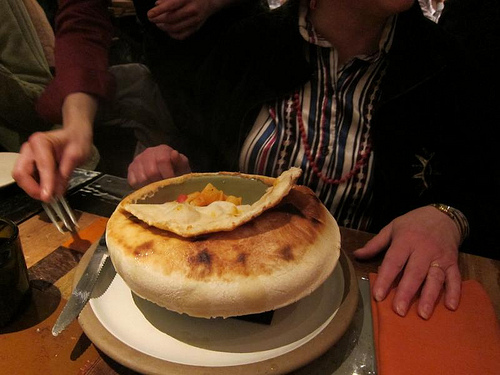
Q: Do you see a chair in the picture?
A: No, there are no chairs.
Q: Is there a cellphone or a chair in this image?
A: No, there are no chairs or cell phones.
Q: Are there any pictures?
A: No, there are no pictures.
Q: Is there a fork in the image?
A: Yes, there is a fork.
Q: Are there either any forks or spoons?
A: Yes, there is a fork.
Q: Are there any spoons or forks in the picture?
A: Yes, there is a fork.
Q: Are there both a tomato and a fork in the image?
A: No, there is a fork but no tomatoes.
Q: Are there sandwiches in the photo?
A: No, there are no sandwiches.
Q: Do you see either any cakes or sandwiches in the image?
A: No, there are no sandwiches or cakes.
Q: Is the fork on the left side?
A: Yes, the fork is on the left of the image.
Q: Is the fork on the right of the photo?
A: No, the fork is on the left of the image.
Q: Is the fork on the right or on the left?
A: The fork is on the left of the image.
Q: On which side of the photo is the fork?
A: The fork is on the left of the image.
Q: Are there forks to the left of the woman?
A: Yes, there is a fork to the left of the woman.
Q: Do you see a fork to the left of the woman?
A: Yes, there is a fork to the left of the woman.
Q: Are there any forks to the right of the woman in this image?
A: No, the fork is to the left of the woman.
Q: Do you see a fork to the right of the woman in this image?
A: No, the fork is to the left of the woman.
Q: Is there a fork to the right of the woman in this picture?
A: No, the fork is to the left of the woman.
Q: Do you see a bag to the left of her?
A: No, there is a fork to the left of the woman.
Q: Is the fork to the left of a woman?
A: Yes, the fork is to the left of a woman.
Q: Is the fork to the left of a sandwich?
A: No, the fork is to the left of a woman.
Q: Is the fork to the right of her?
A: No, the fork is to the left of a woman.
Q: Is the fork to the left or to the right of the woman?
A: The fork is to the left of the woman.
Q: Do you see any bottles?
A: No, there are no bottles.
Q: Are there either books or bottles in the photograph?
A: No, there are no bottles or books.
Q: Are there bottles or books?
A: No, there are no bottles or books.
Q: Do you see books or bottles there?
A: No, there are no bottles or books.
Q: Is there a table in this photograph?
A: Yes, there is a table.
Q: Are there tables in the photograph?
A: Yes, there is a table.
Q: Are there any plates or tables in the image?
A: Yes, there is a table.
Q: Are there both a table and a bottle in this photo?
A: No, there is a table but no bottles.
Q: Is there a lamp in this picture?
A: No, there are no lamps.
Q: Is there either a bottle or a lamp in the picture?
A: No, there are no lamps or bottles.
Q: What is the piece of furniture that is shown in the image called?
A: The piece of furniture is a table.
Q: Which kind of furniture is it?
A: The piece of furniture is a table.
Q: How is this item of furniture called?
A: This is a table.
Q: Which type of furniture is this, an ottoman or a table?
A: This is a table.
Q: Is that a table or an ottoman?
A: That is a table.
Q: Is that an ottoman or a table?
A: That is a table.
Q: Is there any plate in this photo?
A: Yes, there is a plate.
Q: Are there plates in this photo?
A: Yes, there is a plate.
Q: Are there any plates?
A: Yes, there is a plate.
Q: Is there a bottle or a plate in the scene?
A: Yes, there is a plate.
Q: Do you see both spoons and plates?
A: No, there is a plate but no spoons.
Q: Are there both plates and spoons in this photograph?
A: No, there is a plate but no spoons.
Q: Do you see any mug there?
A: No, there are no mugs.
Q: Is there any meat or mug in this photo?
A: No, there are no mugs or meat.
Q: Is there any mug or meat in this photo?
A: No, there are no mugs or meat.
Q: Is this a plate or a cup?
A: This is a plate.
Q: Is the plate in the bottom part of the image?
A: Yes, the plate is in the bottom of the image.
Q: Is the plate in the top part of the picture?
A: No, the plate is in the bottom of the image.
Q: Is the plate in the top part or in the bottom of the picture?
A: The plate is in the bottom of the image.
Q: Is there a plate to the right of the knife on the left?
A: Yes, there is a plate to the right of the knife.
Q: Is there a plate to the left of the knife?
A: No, the plate is to the right of the knife.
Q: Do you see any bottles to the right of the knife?
A: No, there is a plate to the right of the knife.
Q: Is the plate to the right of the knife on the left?
A: Yes, the plate is to the right of the knife.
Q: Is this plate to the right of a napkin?
A: No, the plate is to the right of the knife.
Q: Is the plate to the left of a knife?
A: No, the plate is to the right of a knife.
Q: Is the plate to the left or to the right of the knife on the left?
A: The plate is to the right of the knife.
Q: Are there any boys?
A: No, there are no boys.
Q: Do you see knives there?
A: Yes, there is a knife.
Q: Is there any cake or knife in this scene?
A: Yes, there is a knife.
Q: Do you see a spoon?
A: No, there are no spoons.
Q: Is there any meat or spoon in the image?
A: No, there are no spoons or meat.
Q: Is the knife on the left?
A: Yes, the knife is on the left of the image.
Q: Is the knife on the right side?
A: No, the knife is on the left of the image.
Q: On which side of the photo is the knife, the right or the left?
A: The knife is on the left of the image.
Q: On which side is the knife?
A: The knife is on the left of the image.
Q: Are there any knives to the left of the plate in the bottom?
A: Yes, there is a knife to the left of the plate.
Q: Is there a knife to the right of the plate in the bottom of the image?
A: No, the knife is to the left of the plate.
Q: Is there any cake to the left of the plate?
A: No, there is a knife to the left of the plate.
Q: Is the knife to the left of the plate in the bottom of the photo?
A: Yes, the knife is to the left of the plate.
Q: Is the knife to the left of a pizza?
A: No, the knife is to the left of the plate.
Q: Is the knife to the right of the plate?
A: No, the knife is to the left of the plate.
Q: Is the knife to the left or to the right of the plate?
A: The knife is to the left of the plate.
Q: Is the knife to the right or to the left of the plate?
A: The knife is to the left of the plate.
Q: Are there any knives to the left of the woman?
A: Yes, there is a knife to the left of the woman.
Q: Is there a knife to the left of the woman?
A: Yes, there is a knife to the left of the woman.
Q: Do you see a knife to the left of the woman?
A: Yes, there is a knife to the left of the woman.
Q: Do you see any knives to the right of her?
A: No, the knife is to the left of the woman.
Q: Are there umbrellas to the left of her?
A: No, there is a knife to the left of the woman.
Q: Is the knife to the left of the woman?
A: Yes, the knife is to the left of the woman.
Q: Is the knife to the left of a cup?
A: No, the knife is to the left of the woman.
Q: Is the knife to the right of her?
A: No, the knife is to the left of the woman.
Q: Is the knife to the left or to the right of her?
A: The knife is to the left of the woman.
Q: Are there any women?
A: Yes, there is a woman.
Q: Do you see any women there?
A: Yes, there is a woman.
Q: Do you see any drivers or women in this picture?
A: Yes, there is a woman.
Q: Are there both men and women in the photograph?
A: No, there is a woman but no men.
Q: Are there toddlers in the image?
A: No, there are no toddlers.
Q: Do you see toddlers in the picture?
A: No, there are no toddlers.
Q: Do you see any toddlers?
A: No, there are no toddlers.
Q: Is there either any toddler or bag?
A: No, there are no toddlers or bags.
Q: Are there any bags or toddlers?
A: No, there are no toddlers or bags.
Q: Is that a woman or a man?
A: That is a woman.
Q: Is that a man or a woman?
A: That is a woman.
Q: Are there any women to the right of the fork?
A: Yes, there is a woman to the right of the fork.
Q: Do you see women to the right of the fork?
A: Yes, there is a woman to the right of the fork.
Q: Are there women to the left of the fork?
A: No, the woman is to the right of the fork.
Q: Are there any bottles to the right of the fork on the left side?
A: No, there is a woman to the right of the fork.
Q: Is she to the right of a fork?
A: Yes, the woman is to the right of a fork.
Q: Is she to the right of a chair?
A: No, the woman is to the right of a fork.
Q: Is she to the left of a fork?
A: No, the woman is to the right of a fork.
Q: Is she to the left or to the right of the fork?
A: The woman is to the right of the fork.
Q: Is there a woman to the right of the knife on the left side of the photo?
A: Yes, there is a woman to the right of the knife.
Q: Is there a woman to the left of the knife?
A: No, the woman is to the right of the knife.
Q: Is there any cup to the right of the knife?
A: No, there is a woman to the right of the knife.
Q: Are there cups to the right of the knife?
A: No, there is a woman to the right of the knife.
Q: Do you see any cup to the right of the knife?
A: No, there is a woman to the right of the knife.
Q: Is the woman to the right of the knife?
A: Yes, the woman is to the right of the knife.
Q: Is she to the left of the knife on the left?
A: No, the woman is to the right of the knife.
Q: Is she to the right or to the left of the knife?
A: The woman is to the right of the knife.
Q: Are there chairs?
A: No, there are no chairs.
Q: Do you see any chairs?
A: No, there are no chairs.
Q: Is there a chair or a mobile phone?
A: No, there are no chairs or cell phones.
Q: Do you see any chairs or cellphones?
A: No, there are no chairs or cellphones.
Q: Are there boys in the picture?
A: No, there are no boys.